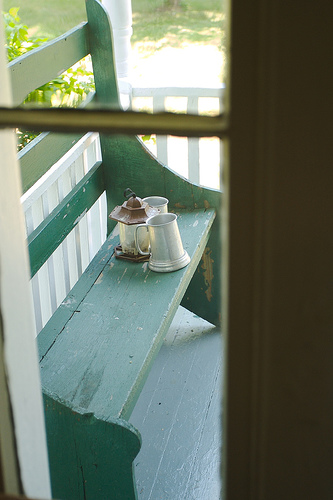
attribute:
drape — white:
[0, 7, 53, 497]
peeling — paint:
[199, 243, 217, 304]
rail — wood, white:
[182, 96, 209, 186]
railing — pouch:
[112, 75, 276, 118]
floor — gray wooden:
[132, 323, 217, 491]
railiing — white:
[131, 83, 224, 118]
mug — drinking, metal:
[141, 195, 168, 214]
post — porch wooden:
[102, 0, 130, 87]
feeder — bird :
[108, 185, 152, 265]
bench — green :
[7, 0, 220, 499]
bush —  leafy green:
[0, 4, 94, 151]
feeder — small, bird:
[112, 192, 170, 268]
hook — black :
[123, 187, 136, 197]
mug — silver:
[135, 209, 191, 277]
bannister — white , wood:
[26, 164, 72, 197]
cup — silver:
[125, 204, 208, 271]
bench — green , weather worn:
[4, 9, 230, 481]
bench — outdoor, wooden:
[9, 40, 269, 353]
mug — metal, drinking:
[126, 213, 191, 273]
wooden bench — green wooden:
[15, 66, 223, 395]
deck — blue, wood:
[148, 320, 233, 498]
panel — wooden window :
[0, 2, 264, 499]